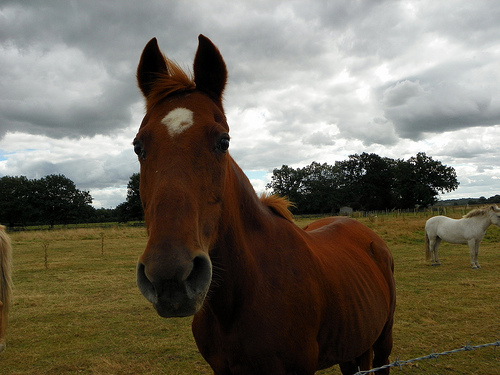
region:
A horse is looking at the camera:
[113, 20, 243, 326]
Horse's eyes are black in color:
[126, 123, 241, 166]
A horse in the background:
[418, 182, 498, 279]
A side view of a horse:
[416, 191, 499, 290]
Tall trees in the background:
[0, 148, 463, 225]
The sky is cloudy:
[1, 0, 497, 195]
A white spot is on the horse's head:
[158, 101, 200, 148]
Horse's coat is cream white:
[414, 188, 499, 278]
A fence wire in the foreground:
[336, 327, 499, 374]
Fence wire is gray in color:
[348, 320, 499, 372]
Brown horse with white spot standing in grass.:
[133, 35, 395, 374]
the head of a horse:
[114, 31, 241, 329]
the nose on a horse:
[129, 238, 219, 319]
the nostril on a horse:
[179, 253, 214, 301]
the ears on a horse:
[131, 31, 229, 100]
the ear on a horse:
[187, 28, 227, 102]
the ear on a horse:
[128, 35, 182, 91]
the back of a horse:
[263, 215, 347, 254]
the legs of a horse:
[427, 239, 484, 264]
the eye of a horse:
[212, 130, 232, 151]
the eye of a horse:
[128, 133, 150, 158]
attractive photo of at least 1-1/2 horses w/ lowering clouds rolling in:
[0, 1, 499, 373]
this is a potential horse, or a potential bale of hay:
[0, 216, 33, 358]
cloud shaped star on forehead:
[153, 104, 200, 143]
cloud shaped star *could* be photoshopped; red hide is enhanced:
[154, 104, 199, 141]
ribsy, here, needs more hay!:
[299, 237, 393, 332]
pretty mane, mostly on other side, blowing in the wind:
[157, 42, 296, 228]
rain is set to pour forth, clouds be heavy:
[0, 0, 499, 197]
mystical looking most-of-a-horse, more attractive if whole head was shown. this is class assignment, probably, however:
[417, 200, 499, 275]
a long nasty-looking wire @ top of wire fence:
[344, 336, 494, 373]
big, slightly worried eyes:
[127, 129, 238, 167]